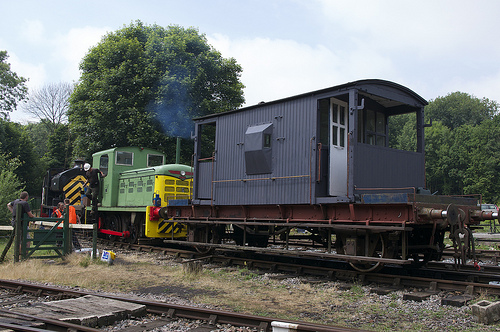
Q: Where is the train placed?
A: On tracks.